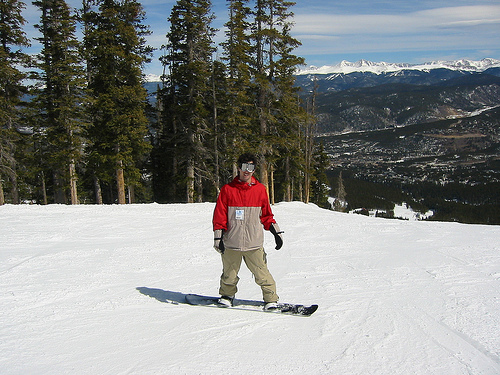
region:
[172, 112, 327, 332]
snowboarder on top of hill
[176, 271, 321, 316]
both feet on snowboard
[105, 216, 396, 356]
flat ground on top of hill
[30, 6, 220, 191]
tall and narrow trees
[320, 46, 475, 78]
snow-capped mountains in distance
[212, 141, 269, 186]
snowboarder wearing goggles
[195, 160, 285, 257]
red and tan jacket with fitted waist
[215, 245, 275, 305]
baggy khaki-colored pants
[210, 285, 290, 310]
white straps over footwear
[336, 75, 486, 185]
different slants on mountains marking elevations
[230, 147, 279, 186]
Person wearing goggles on face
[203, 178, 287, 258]
Person wearing red and gray jacket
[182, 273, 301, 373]
Person standing on snowboard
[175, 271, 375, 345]
Snowboard is white and black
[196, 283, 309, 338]
White brackets on snowboard over top of feet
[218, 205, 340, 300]
Person is wearing black and gray gloves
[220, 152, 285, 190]
Person has black hair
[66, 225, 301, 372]
Ground is covered in snow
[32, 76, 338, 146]
Tall trees in background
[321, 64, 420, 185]
Large mountains in the distance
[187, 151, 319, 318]
snowboarder posing for picture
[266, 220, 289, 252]
glove on man's hand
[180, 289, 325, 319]
snowboard on the ground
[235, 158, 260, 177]
goggles on man's face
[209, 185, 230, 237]
orange sleeve on jacket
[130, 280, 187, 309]
man's shadow in snow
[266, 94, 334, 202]
evergreen trees on side of hill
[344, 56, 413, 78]
snowy mountains on horizon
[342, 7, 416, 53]
clouds over blue daytime sky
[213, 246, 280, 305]
tan snow pants on man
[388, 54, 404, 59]
light blue sky above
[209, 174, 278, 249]
red and beige jacket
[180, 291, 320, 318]
long black ski board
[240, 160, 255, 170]
ski goggles on boys face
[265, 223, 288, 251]
black and beige gloves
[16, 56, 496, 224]
mountains in background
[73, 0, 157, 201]
tall green pine tree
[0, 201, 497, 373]
large area of snow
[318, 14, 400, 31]
white clouds in ski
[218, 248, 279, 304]
beige pair of pants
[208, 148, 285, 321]
The man riding the snowboard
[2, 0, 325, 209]
The trees in the background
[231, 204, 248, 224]
The lift ticket on the boarder's jacket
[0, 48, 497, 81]
The horizon line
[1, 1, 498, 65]
the sky over the mountain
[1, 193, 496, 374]
The snow covering the ground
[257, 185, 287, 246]
The boarder's left arm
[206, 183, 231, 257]
The boarder's right arm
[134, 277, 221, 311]
The shadow of the snowboarder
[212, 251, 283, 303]
The legs of the snowboarder